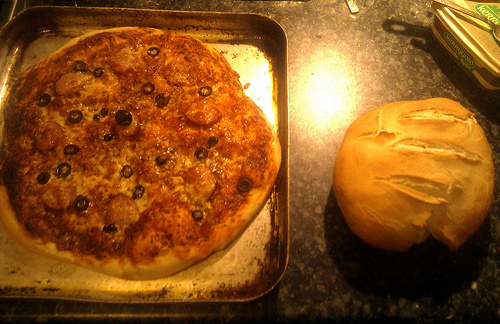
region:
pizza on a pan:
[10, 8, 289, 304]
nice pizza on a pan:
[9, 11, 294, 299]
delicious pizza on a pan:
[5, 4, 308, 303]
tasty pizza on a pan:
[0, 15, 300, 308]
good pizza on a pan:
[6, 8, 296, 294]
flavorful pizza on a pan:
[0, 7, 305, 306]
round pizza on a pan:
[3, 16, 298, 306]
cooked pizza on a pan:
[5, 7, 306, 298]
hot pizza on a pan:
[2, 8, 300, 310]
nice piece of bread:
[334, 83, 496, 268]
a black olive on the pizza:
[138, 78, 158, 99]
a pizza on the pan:
[1, 20, 286, 286]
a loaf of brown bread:
[328, 87, 496, 261]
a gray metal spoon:
[431, 0, 498, 39]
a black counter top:
[1, 0, 496, 322]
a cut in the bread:
[386, 130, 481, 167]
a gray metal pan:
[0, 0, 295, 320]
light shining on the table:
[289, 42, 371, 151]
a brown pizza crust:
[38, 237, 206, 283]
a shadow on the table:
[377, 12, 432, 54]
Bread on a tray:
[2, 6, 285, 301]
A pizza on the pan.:
[10, 30, 262, 265]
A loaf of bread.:
[308, 86, 496, 271]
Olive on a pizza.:
[108, 160, 135, 180]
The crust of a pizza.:
[68, 243, 206, 283]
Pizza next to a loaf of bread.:
[11, 33, 476, 289]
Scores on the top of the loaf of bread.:
[381, 95, 476, 226]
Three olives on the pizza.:
[26, 155, 136, 183]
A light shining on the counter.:
[290, 15, 360, 135]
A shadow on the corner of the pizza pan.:
[235, 8, 291, 55]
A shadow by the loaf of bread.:
[322, 209, 495, 298]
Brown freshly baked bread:
[312, 79, 497, 266]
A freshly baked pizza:
[0, 10, 288, 282]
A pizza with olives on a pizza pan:
[7, 5, 316, 317]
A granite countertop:
[309, 22, 409, 94]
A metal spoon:
[435, 0, 498, 44]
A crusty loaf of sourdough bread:
[317, 87, 487, 260]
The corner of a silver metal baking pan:
[230, 1, 303, 90]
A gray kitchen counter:
[314, 22, 399, 88]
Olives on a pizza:
[137, 79, 169, 114]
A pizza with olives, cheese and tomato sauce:
[30, 20, 275, 275]